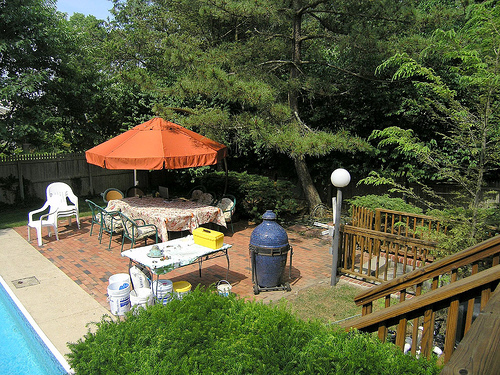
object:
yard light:
[330, 166, 352, 188]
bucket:
[129, 263, 152, 289]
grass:
[263, 279, 447, 345]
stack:
[45, 181, 82, 242]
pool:
[1, 273, 89, 373]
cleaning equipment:
[246, 208, 295, 295]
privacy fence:
[0, 150, 151, 211]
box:
[192, 226, 225, 251]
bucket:
[106, 279, 133, 317]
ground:
[2, 190, 483, 374]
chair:
[24, 195, 62, 248]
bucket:
[215, 279, 233, 299]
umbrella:
[84, 110, 234, 198]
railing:
[326, 263, 500, 370]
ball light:
[328, 166, 353, 190]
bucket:
[107, 272, 132, 285]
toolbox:
[191, 226, 225, 250]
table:
[118, 233, 233, 306]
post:
[329, 187, 346, 287]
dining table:
[95, 190, 229, 243]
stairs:
[322, 232, 500, 369]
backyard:
[0, 185, 500, 375]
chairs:
[99, 187, 126, 205]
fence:
[0, 149, 152, 209]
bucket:
[129, 286, 154, 316]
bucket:
[172, 280, 193, 302]